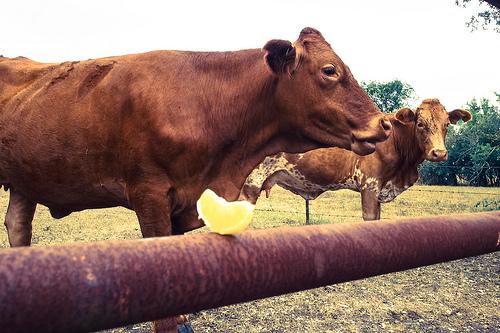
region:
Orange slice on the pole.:
[190, 173, 255, 241]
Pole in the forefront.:
[0, 210, 498, 332]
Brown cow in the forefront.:
[2, 27, 392, 247]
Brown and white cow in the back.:
[236, 94, 470, 234]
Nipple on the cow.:
[257, 177, 277, 197]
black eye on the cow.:
[312, 57, 339, 82]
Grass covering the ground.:
[1, 188, 496, 331]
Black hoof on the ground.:
[173, 315, 195, 331]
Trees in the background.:
[356, 75, 498, 182]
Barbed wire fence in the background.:
[252, 179, 496, 230]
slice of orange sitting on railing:
[194, 188, 255, 236]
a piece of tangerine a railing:
[194, 186, 256, 241]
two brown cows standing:
[0, 25, 474, 242]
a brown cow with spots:
[240, 90, 471, 224]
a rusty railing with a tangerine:
[0, 189, 497, 332]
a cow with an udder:
[232, 92, 472, 240]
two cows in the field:
[0, 23, 475, 248]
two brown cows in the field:
[0, 20, 475, 245]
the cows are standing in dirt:
[0, 27, 471, 332]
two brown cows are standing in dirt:
[1, 25, 472, 331]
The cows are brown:
[22, 71, 468, 239]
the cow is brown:
[0, 50, 335, 212]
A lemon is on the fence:
[170, 192, 265, 232]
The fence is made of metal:
[0, 203, 480, 328]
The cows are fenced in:
[4, 36, 464, 295]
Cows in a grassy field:
[105, 170, 477, 324]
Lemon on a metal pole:
[171, 174, 258, 249]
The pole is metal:
[2, 219, 483, 329]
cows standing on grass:
[10, 126, 457, 311]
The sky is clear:
[3, 0, 492, 120]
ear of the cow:
[263, 37, 303, 79]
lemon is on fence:
[184, 195, 267, 240]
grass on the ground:
[305, 295, 358, 320]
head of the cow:
[400, 97, 458, 164]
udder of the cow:
[236, 174, 299, 195]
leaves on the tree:
[470, 5, 489, 37]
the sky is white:
[332, 3, 412, 45]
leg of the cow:
[345, 188, 389, 217]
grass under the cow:
[87, 219, 111, 234]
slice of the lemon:
[168, 189, 261, 241]